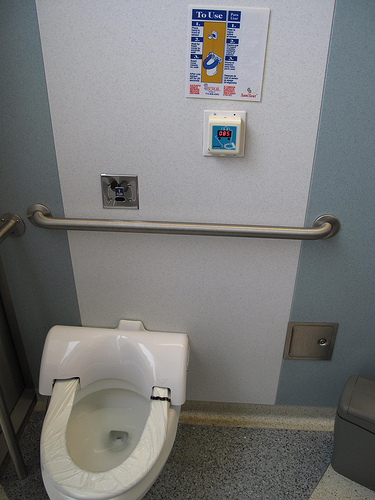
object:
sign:
[184, 5, 272, 101]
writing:
[187, 24, 242, 86]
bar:
[25, 209, 342, 241]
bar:
[3, 210, 28, 242]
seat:
[41, 378, 168, 499]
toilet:
[37, 319, 189, 499]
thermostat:
[203, 107, 247, 159]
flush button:
[97, 174, 138, 211]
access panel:
[280, 320, 338, 363]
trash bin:
[331, 371, 372, 491]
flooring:
[0, 407, 340, 497]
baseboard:
[181, 402, 344, 428]